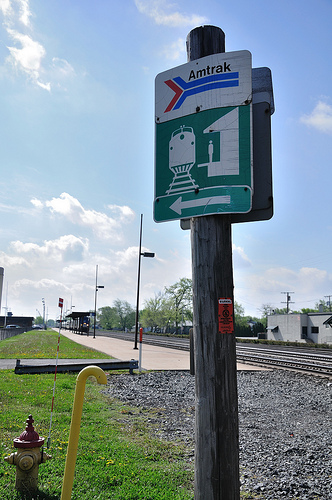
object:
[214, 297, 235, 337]
sticker sign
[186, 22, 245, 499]
post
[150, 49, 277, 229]
train sign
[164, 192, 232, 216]
arrow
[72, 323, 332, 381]
train track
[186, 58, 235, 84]
amtrack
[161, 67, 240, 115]
amtrack logo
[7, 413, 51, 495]
fire hydrant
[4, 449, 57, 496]
bottom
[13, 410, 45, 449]
top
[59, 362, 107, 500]
pipe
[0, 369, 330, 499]
ground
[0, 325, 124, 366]
grass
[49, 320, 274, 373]
platform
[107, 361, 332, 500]
gravel-covered  area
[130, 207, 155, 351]
lamp post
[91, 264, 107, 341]
lamp post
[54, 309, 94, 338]
shelter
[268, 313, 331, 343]
building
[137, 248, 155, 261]
head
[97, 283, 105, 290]
head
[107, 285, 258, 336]
trees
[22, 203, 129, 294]
clouds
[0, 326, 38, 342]
fence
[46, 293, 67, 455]
pole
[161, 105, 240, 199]
station logo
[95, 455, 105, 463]
dandelions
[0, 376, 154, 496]
field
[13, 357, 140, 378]
rail guard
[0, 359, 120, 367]
road